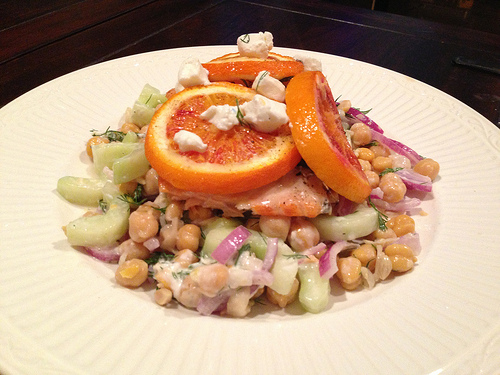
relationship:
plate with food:
[0, 31, 499, 374] [49, 63, 433, 331]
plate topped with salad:
[2, 31, 499, 373] [56, 31, 438, 316]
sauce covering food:
[249, 183, 320, 197] [59, 34, 424, 309]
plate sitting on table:
[2, 31, 499, 373] [0, 41, 497, 372]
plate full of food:
[2, 31, 499, 373] [59, 34, 424, 309]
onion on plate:
[381, 134, 423, 164] [2, 31, 499, 373]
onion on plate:
[211, 223, 251, 267] [2, 31, 499, 373]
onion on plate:
[317, 233, 357, 281] [2, 31, 499, 373]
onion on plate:
[81, 237, 162, 262] [2, 31, 499, 373]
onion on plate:
[399, 162, 434, 197] [2, 31, 499, 373]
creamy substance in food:
[156, 266, 180, 284] [99, 84, 429, 241]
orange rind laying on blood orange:
[159, 160, 299, 194] [146, 80, 298, 192]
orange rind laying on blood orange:
[292, 100, 367, 207] [287, 68, 372, 203]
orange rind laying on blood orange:
[213, 60, 301, 76] [203, 53, 304, 79]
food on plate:
[59, 34, 424, 309] [67, 40, 422, 304]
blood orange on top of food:
[144, 81, 301, 193] [49, 63, 433, 331]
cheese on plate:
[141, 84, 359, 159] [2, 31, 499, 373]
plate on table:
[0, 31, 499, 374] [334, 17, 494, 105]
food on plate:
[55, 31, 442, 317] [2, 31, 499, 373]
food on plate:
[287, 71, 370, 203] [2, 31, 499, 373]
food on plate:
[59, 34, 424, 309] [2, 31, 499, 373]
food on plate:
[55, 31, 442, 317] [15, 22, 490, 361]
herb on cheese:
[224, 93, 252, 131] [150, 14, 307, 158]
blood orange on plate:
[285, 68, 372, 205] [2, 31, 499, 373]